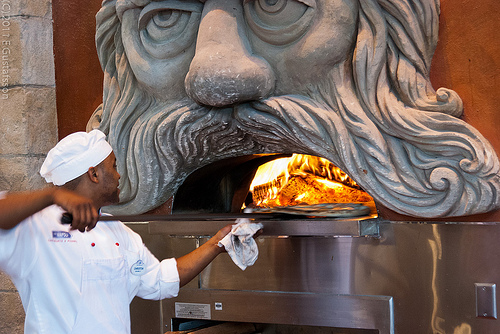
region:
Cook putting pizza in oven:
[35, 120, 162, 326]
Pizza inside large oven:
[260, 188, 385, 219]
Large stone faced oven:
[100, 1, 482, 240]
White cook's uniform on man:
[33, 200, 185, 332]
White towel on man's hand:
[205, 213, 294, 290]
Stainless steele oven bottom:
[98, 218, 470, 332]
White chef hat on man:
[43, 109, 138, 184]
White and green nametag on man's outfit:
[123, 253, 150, 276]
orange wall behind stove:
[435, 13, 498, 85]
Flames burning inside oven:
[248, 153, 390, 212]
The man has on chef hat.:
[13, 121, 107, 191]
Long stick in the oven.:
[67, 200, 389, 236]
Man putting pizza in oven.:
[30, 164, 302, 291]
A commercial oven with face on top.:
[87, 22, 477, 326]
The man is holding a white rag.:
[216, 210, 268, 275]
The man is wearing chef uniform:
[31, 221, 178, 308]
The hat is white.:
[41, 133, 116, 179]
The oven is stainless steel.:
[178, 221, 433, 330]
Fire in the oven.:
[241, 152, 363, 202]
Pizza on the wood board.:
[258, 199, 388, 224]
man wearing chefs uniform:
[21, 120, 167, 328]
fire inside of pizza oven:
[197, 149, 389, 216]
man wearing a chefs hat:
[25, 120, 129, 202]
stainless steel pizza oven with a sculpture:
[143, 0, 465, 319]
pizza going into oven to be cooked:
[248, 181, 377, 246]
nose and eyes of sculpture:
[121, 0, 315, 105]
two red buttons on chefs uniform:
[75, 234, 126, 264]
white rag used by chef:
[212, 200, 282, 281]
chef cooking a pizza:
[19, 120, 401, 322]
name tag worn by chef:
[124, 247, 150, 292]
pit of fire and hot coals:
[249, 150, 366, 217]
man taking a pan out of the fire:
[12, 122, 389, 332]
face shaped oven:
[60, 0, 478, 224]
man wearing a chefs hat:
[6, 133, 187, 331]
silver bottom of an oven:
[81, 203, 498, 332]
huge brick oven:
[69, 3, 492, 332]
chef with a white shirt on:
[3, 126, 184, 332]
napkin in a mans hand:
[219, 205, 265, 268]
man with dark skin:
[5, 121, 135, 263]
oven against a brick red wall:
[54, 4, 498, 247]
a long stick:
[58, 205, 254, 225]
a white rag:
[213, 221, 269, 268]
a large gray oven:
[123, 217, 499, 332]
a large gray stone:
[0, 14, 56, 86]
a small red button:
[88, 238, 98, 250]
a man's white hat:
[36, 128, 117, 189]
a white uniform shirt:
[0, 205, 182, 332]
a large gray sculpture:
[83, 0, 498, 221]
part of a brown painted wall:
[428, 1, 498, 141]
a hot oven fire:
[251, 155, 361, 215]